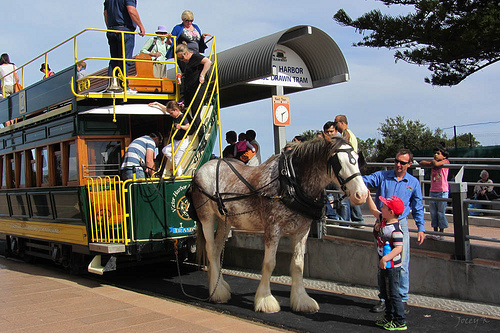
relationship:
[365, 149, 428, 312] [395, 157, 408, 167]
man wearing sunglasses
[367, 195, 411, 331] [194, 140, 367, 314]
kid petting horse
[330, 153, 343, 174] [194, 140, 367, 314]
cover on eyes of horse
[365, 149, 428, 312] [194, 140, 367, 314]
man petting horse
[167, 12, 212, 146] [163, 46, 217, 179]
people going down stairs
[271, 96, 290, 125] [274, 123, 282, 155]
clock on a pole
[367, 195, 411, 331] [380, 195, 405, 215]
kid wearing red cap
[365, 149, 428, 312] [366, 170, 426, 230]
man wearing blue shirt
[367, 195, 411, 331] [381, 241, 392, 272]
kid holding bottle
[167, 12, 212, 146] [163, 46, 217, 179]
people walking down stairs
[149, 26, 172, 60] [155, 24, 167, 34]
person in hat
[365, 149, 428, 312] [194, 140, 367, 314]
man touching horse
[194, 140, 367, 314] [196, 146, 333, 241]
horse with halter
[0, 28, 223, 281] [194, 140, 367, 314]
carriage drawn by horse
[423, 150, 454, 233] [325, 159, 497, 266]
child leaning on fence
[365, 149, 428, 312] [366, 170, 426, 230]
man in blue striped shirt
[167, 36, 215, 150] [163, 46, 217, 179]
people descending stairs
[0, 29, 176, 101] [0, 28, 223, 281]
rail of carriage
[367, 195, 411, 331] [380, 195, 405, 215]
kid with cap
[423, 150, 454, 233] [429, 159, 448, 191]
child in pink shirt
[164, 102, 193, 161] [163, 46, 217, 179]
girl standing on stairs